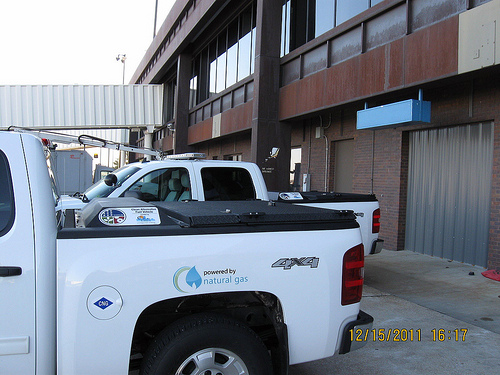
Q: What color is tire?
A: Black.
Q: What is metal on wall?
A: Door.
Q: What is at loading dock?
A: Truck.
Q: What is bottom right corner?
A: Timestamp.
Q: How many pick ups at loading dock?
A: 2.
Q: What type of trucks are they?
A: Work trucks.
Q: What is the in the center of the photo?
A: Truck.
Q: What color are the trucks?
A: White.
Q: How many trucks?
A: Two.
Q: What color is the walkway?
A: Silver.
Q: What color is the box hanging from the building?
A: Blue.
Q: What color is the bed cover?
A: Black.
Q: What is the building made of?
A: Brick.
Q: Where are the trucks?
A: Parked in front of building.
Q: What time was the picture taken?
A: 15:17.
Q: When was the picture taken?
A: Daytime.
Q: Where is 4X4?
A: On the side of truck.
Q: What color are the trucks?
A: White.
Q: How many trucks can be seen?
A: 2.